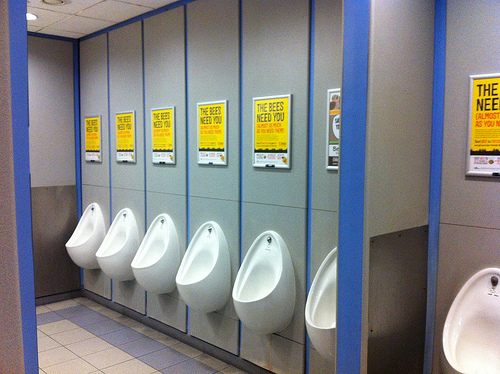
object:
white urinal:
[64, 202, 108, 272]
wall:
[74, 0, 497, 371]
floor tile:
[35, 296, 246, 372]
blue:
[7, 0, 44, 372]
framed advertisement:
[251, 93, 292, 171]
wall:
[368, 225, 430, 374]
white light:
[26, 13, 37, 22]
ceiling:
[26, 0, 179, 39]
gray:
[251, 6, 300, 76]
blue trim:
[336, 1, 372, 373]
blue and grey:
[40, 296, 225, 369]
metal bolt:
[90, 204, 95, 212]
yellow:
[256, 100, 287, 148]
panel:
[239, 1, 311, 373]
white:
[77, 243, 90, 256]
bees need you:
[256, 101, 285, 123]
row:
[64, 199, 333, 366]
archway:
[2, 0, 366, 374]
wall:
[344, 0, 448, 368]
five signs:
[86, 93, 294, 169]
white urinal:
[172, 216, 227, 318]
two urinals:
[172, 211, 296, 335]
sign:
[83, 113, 110, 162]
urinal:
[91, 205, 141, 284]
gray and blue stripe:
[133, 20, 179, 106]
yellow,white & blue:
[74, 120, 97, 157]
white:
[112, 256, 125, 270]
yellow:
[86, 118, 89, 147]